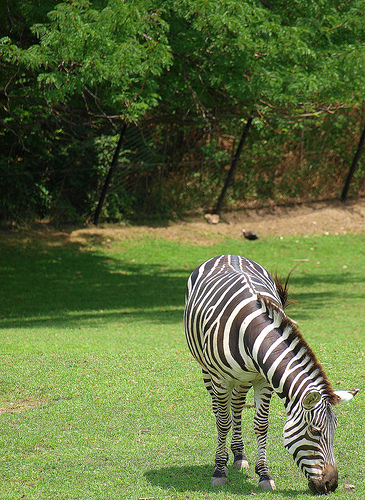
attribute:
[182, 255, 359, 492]
zebra — grazing, striped, white, black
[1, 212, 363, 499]
grass — field, green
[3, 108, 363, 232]
fence — leaning, metal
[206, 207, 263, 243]
rocks — small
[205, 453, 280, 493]
hooves — white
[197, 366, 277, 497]
legs — stirped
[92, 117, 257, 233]
posts — black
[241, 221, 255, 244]
rock — brown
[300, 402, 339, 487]
face — down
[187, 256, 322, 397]
stripes — black, white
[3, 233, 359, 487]
grass — green